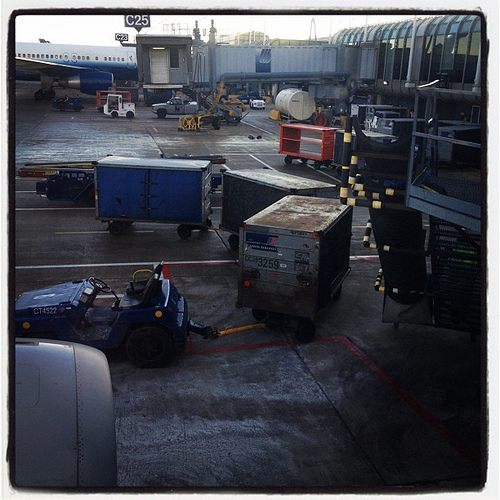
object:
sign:
[124, 15, 151, 32]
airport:
[14, 16, 484, 489]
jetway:
[17, 83, 114, 103]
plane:
[15, 42, 138, 102]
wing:
[15, 56, 100, 71]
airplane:
[15, 39, 138, 102]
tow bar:
[216, 321, 267, 339]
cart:
[16, 257, 216, 367]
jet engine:
[15, 335, 117, 489]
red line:
[339, 333, 488, 481]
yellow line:
[55, 229, 98, 236]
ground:
[10, 87, 500, 500]